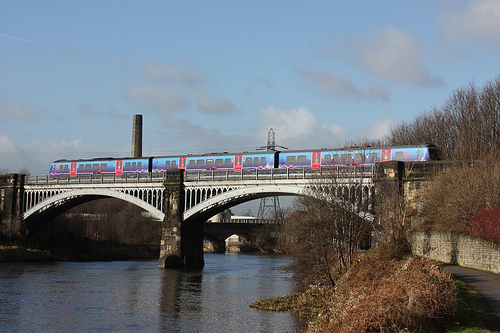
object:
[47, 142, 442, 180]
train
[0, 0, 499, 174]
sky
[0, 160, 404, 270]
bridge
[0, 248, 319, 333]
water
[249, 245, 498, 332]
grass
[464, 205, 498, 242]
branches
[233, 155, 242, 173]
door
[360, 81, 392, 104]
clouds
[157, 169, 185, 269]
column